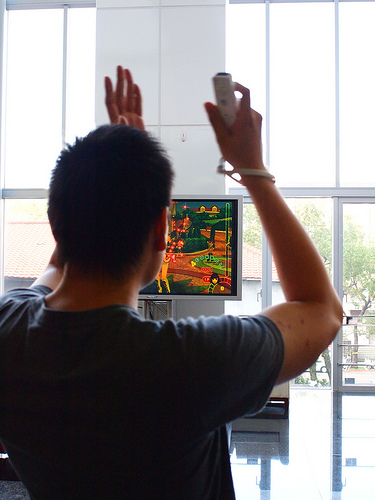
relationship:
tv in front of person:
[117, 186, 244, 304] [1, 64, 345, 500]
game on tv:
[138, 201, 235, 294] [117, 186, 244, 304]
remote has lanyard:
[211, 71, 238, 134] [215, 157, 274, 182]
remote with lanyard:
[211, 71, 238, 134] [215, 157, 274, 182]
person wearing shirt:
[1, 64, 345, 500] [3, 284, 284, 499]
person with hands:
[1, 64, 345, 500] [202, 83, 264, 169]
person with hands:
[1, 64, 345, 500] [101, 65, 147, 140]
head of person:
[41, 120, 174, 296] [1, 64, 345, 500]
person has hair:
[1, 64, 345, 500] [44, 123, 174, 261]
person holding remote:
[1, 64, 345, 500] [211, 71, 238, 134]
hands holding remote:
[202, 83, 264, 169] [211, 71, 238, 134]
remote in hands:
[211, 71, 238, 134] [202, 83, 264, 169]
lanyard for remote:
[215, 157, 274, 182] [211, 71, 238, 134]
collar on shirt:
[30, 295, 140, 324] [3, 284, 284, 499]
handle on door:
[343, 314, 351, 323] [327, 197, 375, 392]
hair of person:
[44, 123, 174, 261] [1, 64, 345, 500]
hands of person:
[101, 65, 147, 140] [1, 64, 345, 500]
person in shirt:
[1, 64, 345, 500] [3, 284, 284, 499]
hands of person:
[202, 83, 264, 169] [1, 64, 345, 500]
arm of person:
[204, 157, 346, 423] [1, 64, 345, 500]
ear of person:
[154, 205, 168, 257] [1, 64, 345, 500]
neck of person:
[48, 262, 143, 315] [1, 64, 345, 500]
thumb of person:
[202, 101, 228, 139] [1, 64, 345, 500]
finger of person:
[233, 79, 252, 114] [1, 64, 345, 500]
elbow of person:
[333, 297, 345, 329] [1, 64, 345, 500]